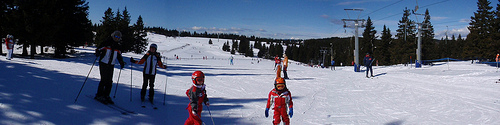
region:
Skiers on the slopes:
[81, 33, 297, 95]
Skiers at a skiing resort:
[67, 23, 209, 113]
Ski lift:
[336, 10, 386, 86]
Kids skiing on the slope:
[179, 74, 314, 124]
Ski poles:
[125, 48, 199, 103]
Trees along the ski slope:
[227, 35, 349, 115]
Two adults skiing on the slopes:
[65, 16, 216, 118]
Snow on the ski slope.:
[171, 25, 247, 72]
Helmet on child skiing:
[188, 71, 198, 84]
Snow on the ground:
[204, 50, 239, 85]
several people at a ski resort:
[94, 29, 495, 124]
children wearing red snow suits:
[186, 61, 353, 122]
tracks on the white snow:
[323, 76, 400, 118]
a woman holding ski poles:
[126, 41, 166, 116]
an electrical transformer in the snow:
[340, 0, 362, 79]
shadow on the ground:
[6, 54, 66, 111]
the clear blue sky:
[175, 7, 308, 22]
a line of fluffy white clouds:
[186, 21, 253, 31]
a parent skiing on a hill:
[76, 26, 131, 110]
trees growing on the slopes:
[224, 36, 284, 53]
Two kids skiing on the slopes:
[174, 62, 341, 123]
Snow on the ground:
[199, 37, 269, 118]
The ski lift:
[331, 14, 398, 78]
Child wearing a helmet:
[269, 60, 294, 119]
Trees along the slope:
[111, 20, 313, 80]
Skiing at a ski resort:
[35, 21, 247, 113]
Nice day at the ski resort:
[123, 7, 310, 114]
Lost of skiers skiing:
[36, 20, 411, 92]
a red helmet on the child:
[191, 67, 206, 87]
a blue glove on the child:
[262, 107, 271, 115]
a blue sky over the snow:
[0, 0, 499, 42]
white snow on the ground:
[0, 30, 499, 123]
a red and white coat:
[263, 87, 295, 112]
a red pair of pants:
[268, 109, 291, 124]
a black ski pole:
[68, 55, 99, 106]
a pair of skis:
[88, 91, 138, 118]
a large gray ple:
[340, 17, 367, 72]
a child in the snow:
[263, 74, 295, 124]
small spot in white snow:
[322, 107, 360, 123]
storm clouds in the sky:
[184, 16, 280, 41]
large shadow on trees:
[8, 51, 152, 120]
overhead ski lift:
[328, 2, 385, 35]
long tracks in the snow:
[389, 70, 499, 104]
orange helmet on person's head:
[260, 70, 304, 96]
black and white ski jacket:
[138, 52, 177, 85]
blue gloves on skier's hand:
[255, 100, 319, 119]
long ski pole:
[63, 47, 121, 124]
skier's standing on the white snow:
[76, 23, 327, 120]